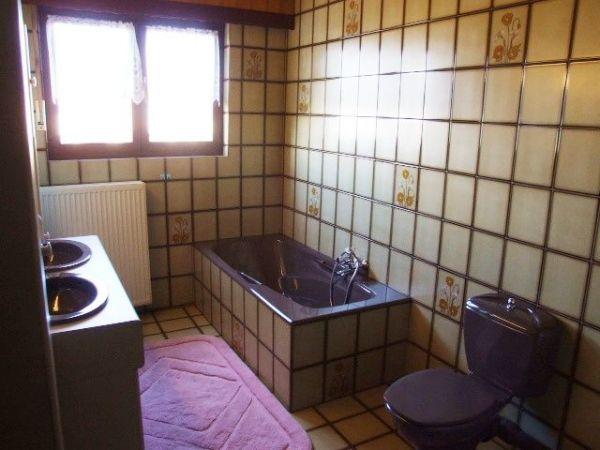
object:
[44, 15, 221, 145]
sunlight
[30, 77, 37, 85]
knob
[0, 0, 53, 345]
cabinet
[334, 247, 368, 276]
faucet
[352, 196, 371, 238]
tile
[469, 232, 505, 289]
tile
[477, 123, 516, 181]
tile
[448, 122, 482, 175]
tile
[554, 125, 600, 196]
tile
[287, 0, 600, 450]
wall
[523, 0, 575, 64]
tile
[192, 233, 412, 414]
bathtub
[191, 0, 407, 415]
corner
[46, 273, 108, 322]
sink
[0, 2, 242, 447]
left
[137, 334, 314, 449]
carpet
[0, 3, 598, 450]
bathroom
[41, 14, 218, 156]
window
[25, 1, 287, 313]
background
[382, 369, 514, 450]
bowl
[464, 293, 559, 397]
cistern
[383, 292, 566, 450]
system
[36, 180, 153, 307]
radiator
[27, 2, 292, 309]
wall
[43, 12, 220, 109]
curtains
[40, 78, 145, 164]
counter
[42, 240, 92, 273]
sink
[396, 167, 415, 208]
pattern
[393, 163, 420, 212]
tile